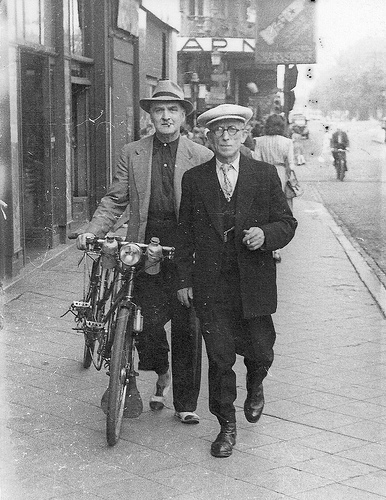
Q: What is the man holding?
A: Bike.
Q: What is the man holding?
A: Bicycle.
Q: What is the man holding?
A: Cycle.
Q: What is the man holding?
A: Bicycle.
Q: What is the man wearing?
A: Hat.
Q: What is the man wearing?
A: Hat.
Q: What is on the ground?
A: Pavement.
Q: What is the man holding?
A: Bicycle.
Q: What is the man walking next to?
A: A bike.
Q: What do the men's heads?
A: Hats.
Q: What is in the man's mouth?
A: A cigarette.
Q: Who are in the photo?
A: People.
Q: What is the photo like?
A: Black and white.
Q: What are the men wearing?
A: Hats.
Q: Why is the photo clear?
A: Its during the day.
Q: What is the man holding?
A: A bicycle.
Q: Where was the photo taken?
A: On a city sidewalk.